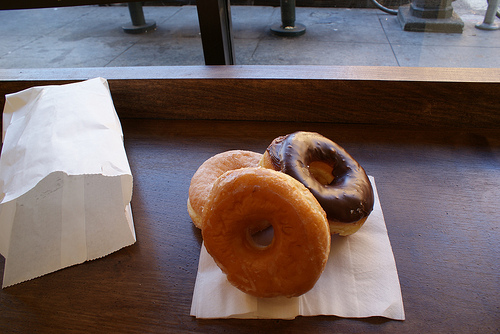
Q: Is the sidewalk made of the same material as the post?
A: No, the sidewalk is made of cement and the post is made of metal.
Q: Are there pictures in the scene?
A: No, there are no pictures.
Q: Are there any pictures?
A: No, there are no pictures.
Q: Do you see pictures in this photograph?
A: No, there are no pictures.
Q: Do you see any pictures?
A: No, there are no pictures.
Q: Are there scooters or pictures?
A: No, there are no pictures or scooters.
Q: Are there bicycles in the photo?
A: Yes, there is a bicycle.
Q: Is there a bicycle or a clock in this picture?
A: Yes, there is a bicycle.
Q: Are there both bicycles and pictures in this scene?
A: No, there is a bicycle but no pictures.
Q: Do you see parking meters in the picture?
A: No, there are no parking meters.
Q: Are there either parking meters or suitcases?
A: No, there are no parking meters or suitcases.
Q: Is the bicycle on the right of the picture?
A: Yes, the bicycle is on the right of the image.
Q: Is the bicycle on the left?
A: No, the bicycle is on the right of the image.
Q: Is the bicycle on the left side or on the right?
A: The bicycle is on the right of the image.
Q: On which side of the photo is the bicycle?
A: The bicycle is on the right of the image.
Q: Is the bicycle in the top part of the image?
A: Yes, the bicycle is in the top of the image.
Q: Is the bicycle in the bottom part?
A: No, the bicycle is in the top of the image.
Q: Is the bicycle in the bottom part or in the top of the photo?
A: The bicycle is in the top of the image.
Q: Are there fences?
A: No, there are no fences.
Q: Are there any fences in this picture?
A: No, there are no fences.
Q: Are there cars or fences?
A: No, there are no fences or cars.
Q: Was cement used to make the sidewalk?
A: Yes, the sidewalk is made of cement.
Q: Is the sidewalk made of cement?
A: Yes, the sidewalk is made of cement.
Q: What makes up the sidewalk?
A: The sidewalk is made of cement.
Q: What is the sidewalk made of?
A: The sidewalk is made of concrete.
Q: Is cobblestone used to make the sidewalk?
A: No, the sidewalk is made of cement.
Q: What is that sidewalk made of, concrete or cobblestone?
A: The sidewalk is made of concrete.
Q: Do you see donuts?
A: Yes, there is a donut.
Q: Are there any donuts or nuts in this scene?
A: Yes, there is a donut.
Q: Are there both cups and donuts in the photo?
A: No, there is a donut but no cups.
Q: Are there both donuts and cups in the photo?
A: No, there is a donut but no cups.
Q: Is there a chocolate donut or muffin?
A: Yes, there is a chocolate donut.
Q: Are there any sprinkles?
A: No, there are no sprinkles.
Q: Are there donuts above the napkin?
A: Yes, there is a donut above the napkin.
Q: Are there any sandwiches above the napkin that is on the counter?
A: No, there is a donut above the napkin.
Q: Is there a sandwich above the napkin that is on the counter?
A: No, there is a donut above the napkin.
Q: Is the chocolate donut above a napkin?
A: Yes, the doughnut is above a napkin.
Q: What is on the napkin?
A: The doughnut is on the napkin.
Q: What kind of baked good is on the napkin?
A: The food is a donut.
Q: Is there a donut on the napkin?
A: Yes, there is a donut on the napkin.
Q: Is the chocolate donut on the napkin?
A: Yes, the doughnut is on the napkin.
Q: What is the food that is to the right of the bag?
A: The food is a donut.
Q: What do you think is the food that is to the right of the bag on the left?
A: The food is a donut.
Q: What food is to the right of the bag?
A: The food is a donut.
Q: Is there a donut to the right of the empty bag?
A: Yes, there is a donut to the right of the bag.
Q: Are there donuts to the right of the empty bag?
A: Yes, there is a donut to the right of the bag.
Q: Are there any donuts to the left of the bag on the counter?
A: No, the donut is to the right of the bag.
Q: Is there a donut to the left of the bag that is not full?
A: No, the donut is to the right of the bag.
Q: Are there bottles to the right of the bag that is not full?
A: No, there is a donut to the right of the bag.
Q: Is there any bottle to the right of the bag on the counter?
A: No, there is a donut to the right of the bag.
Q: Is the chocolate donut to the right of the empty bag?
A: Yes, the donut is to the right of the bag.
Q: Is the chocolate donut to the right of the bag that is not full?
A: Yes, the donut is to the right of the bag.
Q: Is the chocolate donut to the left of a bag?
A: No, the donut is to the right of a bag.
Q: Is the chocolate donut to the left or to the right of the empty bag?
A: The donut is to the right of the bag.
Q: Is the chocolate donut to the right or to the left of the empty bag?
A: The donut is to the right of the bag.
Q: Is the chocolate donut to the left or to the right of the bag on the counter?
A: The donut is to the right of the bag.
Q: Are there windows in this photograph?
A: Yes, there is a window.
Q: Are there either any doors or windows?
A: Yes, there is a window.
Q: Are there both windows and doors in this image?
A: No, there is a window but no doors.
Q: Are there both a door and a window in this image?
A: No, there is a window but no doors.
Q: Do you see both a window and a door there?
A: No, there is a window but no doors.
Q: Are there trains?
A: No, there are no trains.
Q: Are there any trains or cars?
A: No, there are no trains or cars.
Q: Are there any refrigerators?
A: No, there are no refrigerators.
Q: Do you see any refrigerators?
A: No, there are no refrigerators.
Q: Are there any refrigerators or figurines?
A: No, there are no refrigerators or figurines.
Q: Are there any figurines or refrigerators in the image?
A: No, there are no refrigerators or figurines.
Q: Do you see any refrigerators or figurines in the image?
A: No, there are no refrigerators or figurines.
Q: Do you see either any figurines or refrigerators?
A: No, there are no refrigerators or figurines.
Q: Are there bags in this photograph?
A: Yes, there is a bag.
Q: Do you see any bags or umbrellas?
A: Yes, there is a bag.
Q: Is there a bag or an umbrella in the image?
A: Yes, there is a bag.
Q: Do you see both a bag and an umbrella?
A: No, there is a bag but no umbrellas.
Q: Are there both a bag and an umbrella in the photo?
A: No, there is a bag but no umbrellas.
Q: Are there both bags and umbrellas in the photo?
A: No, there is a bag but no umbrellas.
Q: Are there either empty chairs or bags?
A: Yes, there is an empty bag.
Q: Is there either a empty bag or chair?
A: Yes, there is an empty bag.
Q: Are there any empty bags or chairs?
A: Yes, there is an empty bag.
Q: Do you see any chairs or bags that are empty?
A: Yes, the bag is empty.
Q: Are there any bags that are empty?
A: Yes, there is an empty bag.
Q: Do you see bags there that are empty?
A: Yes, there is a bag that is empty.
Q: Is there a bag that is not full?
A: Yes, there is a empty bag.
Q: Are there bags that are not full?
A: Yes, there is a empty bag.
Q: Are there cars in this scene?
A: No, there are no cars.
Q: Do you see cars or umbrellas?
A: No, there are no cars or umbrellas.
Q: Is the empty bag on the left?
A: Yes, the bag is on the left of the image.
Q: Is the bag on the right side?
A: No, the bag is on the left of the image.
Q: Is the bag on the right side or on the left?
A: The bag is on the left of the image.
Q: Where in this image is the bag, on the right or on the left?
A: The bag is on the left of the image.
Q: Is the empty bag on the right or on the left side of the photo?
A: The bag is on the left of the image.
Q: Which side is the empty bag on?
A: The bag is on the left of the image.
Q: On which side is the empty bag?
A: The bag is on the left of the image.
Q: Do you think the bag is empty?
A: Yes, the bag is empty.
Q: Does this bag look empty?
A: Yes, the bag is empty.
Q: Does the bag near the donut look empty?
A: Yes, the bag is empty.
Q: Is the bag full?
A: No, the bag is empty.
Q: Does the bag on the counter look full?
A: No, the bag is empty.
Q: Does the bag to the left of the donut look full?
A: No, the bag is empty.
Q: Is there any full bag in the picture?
A: No, there is a bag but it is empty.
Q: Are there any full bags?
A: No, there is a bag but it is empty.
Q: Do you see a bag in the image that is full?
A: No, there is a bag but it is empty.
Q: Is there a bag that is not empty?
A: No, there is a bag but it is empty.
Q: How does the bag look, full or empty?
A: The bag is empty.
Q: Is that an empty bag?
A: Yes, that is an empty bag.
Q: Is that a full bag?
A: No, that is an empty bag.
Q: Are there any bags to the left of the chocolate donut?
A: Yes, there is a bag to the left of the doughnut.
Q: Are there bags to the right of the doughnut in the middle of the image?
A: No, the bag is to the left of the doughnut.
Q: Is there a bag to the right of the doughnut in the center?
A: No, the bag is to the left of the doughnut.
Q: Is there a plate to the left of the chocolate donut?
A: No, there is a bag to the left of the doughnut.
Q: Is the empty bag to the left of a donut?
A: Yes, the bag is to the left of a donut.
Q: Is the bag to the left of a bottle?
A: No, the bag is to the left of a donut.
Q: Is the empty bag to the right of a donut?
A: No, the bag is to the left of a donut.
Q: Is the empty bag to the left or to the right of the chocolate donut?
A: The bag is to the left of the doughnut.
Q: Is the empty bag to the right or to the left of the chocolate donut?
A: The bag is to the left of the doughnut.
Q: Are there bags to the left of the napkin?
A: Yes, there is a bag to the left of the napkin.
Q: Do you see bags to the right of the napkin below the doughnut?
A: No, the bag is to the left of the napkin.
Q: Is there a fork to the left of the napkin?
A: No, there is a bag to the left of the napkin.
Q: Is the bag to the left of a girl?
A: No, the bag is to the left of the napkin.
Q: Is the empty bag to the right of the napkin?
A: No, the bag is to the left of the napkin.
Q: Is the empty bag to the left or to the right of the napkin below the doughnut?
A: The bag is to the left of the napkin.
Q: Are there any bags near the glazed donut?
A: Yes, there is a bag near the donut.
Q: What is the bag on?
A: The bag is on the counter.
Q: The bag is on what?
A: The bag is on the counter.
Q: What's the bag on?
A: The bag is on the counter.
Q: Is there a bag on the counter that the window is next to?
A: Yes, there is a bag on the counter.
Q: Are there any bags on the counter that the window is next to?
A: Yes, there is a bag on the counter.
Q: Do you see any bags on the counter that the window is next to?
A: Yes, there is a bag on the counter.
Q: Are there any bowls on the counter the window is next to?
A: No, there is a bag on the counter.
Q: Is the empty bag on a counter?
A: Yes, the bag is on a counter.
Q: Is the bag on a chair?
A: No, the bag is on a counter.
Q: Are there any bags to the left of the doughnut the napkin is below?
A: Yes, there is a bag to the left of the doughnut.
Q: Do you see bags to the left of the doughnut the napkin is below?
A: Yes, there is a bag to the left of the doughnut.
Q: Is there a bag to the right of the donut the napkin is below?
A: No, the bag is to the left of the donut.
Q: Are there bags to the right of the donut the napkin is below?
A: No, the bag is to the left of the donut.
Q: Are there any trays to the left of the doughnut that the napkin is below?
A: No, there is a bag to the left of the donut.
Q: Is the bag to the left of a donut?
A: Yes, the bag is to the left of a donut.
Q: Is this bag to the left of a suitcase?
A: No, the bag is to the left of a donut.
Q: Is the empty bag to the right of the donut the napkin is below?
A: No, the bag is to the left of the donut.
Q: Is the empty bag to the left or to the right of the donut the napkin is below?
A: The bag is to the left of the donut.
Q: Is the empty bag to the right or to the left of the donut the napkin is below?
A: The bag is to the left of the donut.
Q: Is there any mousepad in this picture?
A: No, there are no mouse pads.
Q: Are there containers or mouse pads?
A: No, there are no mouse pads or containers.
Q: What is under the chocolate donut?
A: The napkin is under the donut.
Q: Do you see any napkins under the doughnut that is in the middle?
A: Yes, there is a napkin under the donut.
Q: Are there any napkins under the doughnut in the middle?
A: Yes, there is a napkin under the donut.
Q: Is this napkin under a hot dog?
A: No, the napkin is under the doughnut.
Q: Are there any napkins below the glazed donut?
A: Yes, there is a napkin below the donut.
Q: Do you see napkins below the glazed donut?
A: Yes, there is a napkin below the donut.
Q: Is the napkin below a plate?
A: No, the napkin is below the donut.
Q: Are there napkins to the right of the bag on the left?
A: Yes, there is a napkin to the right of the bag.